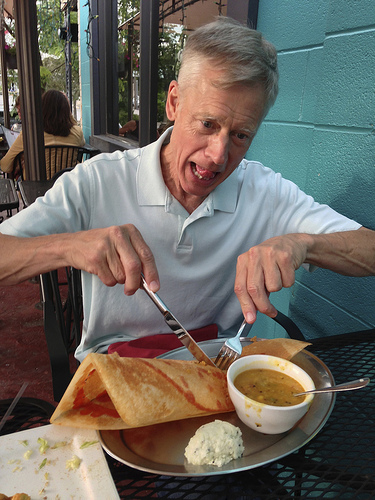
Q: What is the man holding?
A: A knife and fork.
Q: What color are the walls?
A: Blue.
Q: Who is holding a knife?
A: A man.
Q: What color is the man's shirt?
A: White.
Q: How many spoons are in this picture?
A: One.